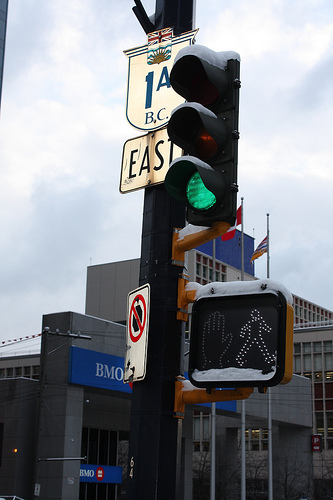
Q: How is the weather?
A: It is cloudy.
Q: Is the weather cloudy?
A: Yes, it is cloudy.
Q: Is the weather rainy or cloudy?
A: It is cloudy.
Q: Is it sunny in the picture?
A: No, it is cloudy.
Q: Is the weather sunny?
A: No, it is cloudy.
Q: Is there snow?
A: Yes, there is snow.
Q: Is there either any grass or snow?
A: Yes, there is snow.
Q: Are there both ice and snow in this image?
A: No, there is snow but no ice.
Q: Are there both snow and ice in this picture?
A: No, there is snow but no ice.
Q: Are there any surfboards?
A: No, there are no surfboards.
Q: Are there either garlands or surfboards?
A: No, there are no surfboards or garlands.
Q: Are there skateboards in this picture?
A: No, there are no skateboards.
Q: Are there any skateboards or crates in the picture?
A: No, there are no skateboards or crates.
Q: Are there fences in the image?
A: No, there are no fences.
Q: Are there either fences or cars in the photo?
A: No, there are no fences or cars.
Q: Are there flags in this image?
A: Yes, there is a flag.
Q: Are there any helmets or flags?
A: Yes, there is a flag.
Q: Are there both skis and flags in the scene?
A: No, there is a flag but no skis.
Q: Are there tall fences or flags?
A: Yes, there is a tall flag.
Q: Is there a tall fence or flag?
A: Yes, there is a tall flag.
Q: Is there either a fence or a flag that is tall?
A: Yes, the flag is tall.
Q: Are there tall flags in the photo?
A: Yes, there is a tall flag.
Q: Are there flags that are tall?
A: Yes, there is a tall flag.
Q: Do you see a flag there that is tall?
A: Yes, there is a flag that is tall.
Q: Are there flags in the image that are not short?
A: Yes, there is a tall flag.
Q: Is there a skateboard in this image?
A: No, there are no skateboards.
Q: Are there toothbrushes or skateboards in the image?
A: No, there are no skateboards or toothbrushes.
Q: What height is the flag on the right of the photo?
A: The flag is tall.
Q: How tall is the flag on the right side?
A: The flag is tall.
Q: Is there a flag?
A: Yes, there is a flag.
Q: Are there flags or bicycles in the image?
A: Yes, there is a flag.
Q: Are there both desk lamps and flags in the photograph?
A: No, there is a flag but no desk lamps.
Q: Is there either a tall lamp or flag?
A: Yes, there is a tall flag.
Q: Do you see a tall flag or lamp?
A: Yes, there is a tall flag.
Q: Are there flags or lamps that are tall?
A: Yes, the flag is tall.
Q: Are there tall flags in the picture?
A: Yes, there is a tall flag.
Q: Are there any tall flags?
A: Yes, there is a tall flag.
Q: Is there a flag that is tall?
A: Yes, there is a flag that is tall.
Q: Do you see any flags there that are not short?
A: Yes, there is a tall flag.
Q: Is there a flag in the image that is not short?
A: Yes, there is a tall flag.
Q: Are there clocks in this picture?
A: No, there are no clocks.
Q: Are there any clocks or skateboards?
A: No, there are no clocks or skateboards.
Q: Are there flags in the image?
A: Yes, there is a flag.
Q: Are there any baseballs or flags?
A: Yes, there is a flag.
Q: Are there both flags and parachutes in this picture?
A: No, there is a flag but no parachutes.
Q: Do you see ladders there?
A: No, there are no ladders.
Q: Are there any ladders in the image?
A: No, there are no ladders.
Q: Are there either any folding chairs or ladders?
A: No, there are no ladders or folding chairs.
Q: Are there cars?
A: No, there are no cars.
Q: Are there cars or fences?
A: No, there are no cars or fences.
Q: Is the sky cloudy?
A: Yes, the sky is cloudy.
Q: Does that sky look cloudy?
A: Yes, the sky is cloudy.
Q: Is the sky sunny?
A: No, the sky is cloudy.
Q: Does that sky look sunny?
A: No, the sky is cloudy.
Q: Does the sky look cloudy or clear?
A: The sky is cloudy.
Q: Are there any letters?
A: Yes, there are letters.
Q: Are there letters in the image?
A: Yes, there are letters.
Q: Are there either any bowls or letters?
A: Yes, there are letters.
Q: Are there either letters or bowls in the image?
A: Yes, there are letters.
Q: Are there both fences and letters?
A: No, there are letters but no fences.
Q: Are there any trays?
A: No, there are no trays.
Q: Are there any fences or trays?
A: No, there are no trays or fences.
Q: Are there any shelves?
A: No, there are no shelves.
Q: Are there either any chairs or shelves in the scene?
A: No, there are no shelves or chairs.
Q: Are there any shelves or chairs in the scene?
A: No, there are no shelves or chairs.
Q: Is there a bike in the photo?
A: No, there are no bikes.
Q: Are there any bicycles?
A: No, there are no bicycles.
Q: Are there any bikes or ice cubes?
A: No, there are no bikes or ice cubes.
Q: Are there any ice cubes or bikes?
A: No, there are no bikes or ice cubes.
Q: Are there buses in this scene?
A: No, there are no buses.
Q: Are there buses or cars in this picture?
A: No, there are no buses or cars.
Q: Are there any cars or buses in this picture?
A: No, there are no buses or cars.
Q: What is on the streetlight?
A: The sign is on the streetlight.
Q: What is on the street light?
A: The sign is on the streetlight.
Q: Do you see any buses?
A: No, there are no buses.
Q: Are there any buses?
A: No, there are no buses.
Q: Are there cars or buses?
A: No, there are no buses or cars.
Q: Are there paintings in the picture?
A: No, there are no paintings.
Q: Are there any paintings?
A: No, there are no paintings.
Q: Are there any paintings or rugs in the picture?
A: No, there are no paintings or rugs.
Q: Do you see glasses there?
A: No, there are no glasses.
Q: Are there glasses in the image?
A: No, there are no glasses.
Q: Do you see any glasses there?
A: No, there are no glasses.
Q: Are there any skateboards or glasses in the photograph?
A: No, there are no glasses or skateboards.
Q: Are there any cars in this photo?
A: No, there are no cars.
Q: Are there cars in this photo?
A: No, there are no cars.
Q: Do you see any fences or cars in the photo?
A: No, there are no cars or fences.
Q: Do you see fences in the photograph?
A: No, there are no fences.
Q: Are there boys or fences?
A: No, there are no fences or boys.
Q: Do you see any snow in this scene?
A: Yes, there is snow.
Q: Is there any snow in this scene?
A: Yes, there is snow.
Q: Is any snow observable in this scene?
A: Yes, there is snow.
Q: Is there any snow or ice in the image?
A: Yes, there is snow.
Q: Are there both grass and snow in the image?
A: No, there is snow but no grass.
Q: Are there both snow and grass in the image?
A: No, there is snow but no grass.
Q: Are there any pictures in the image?
A: No, there are no pictures.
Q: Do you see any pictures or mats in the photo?
A: No, there are no pictures or mats.